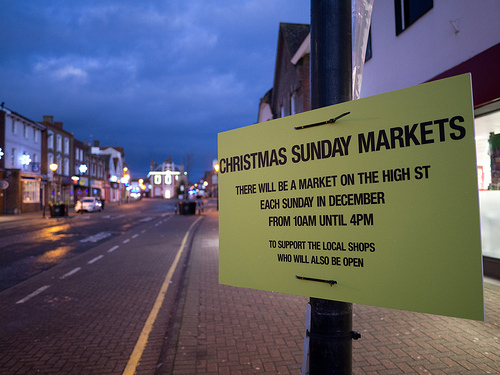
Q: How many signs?
A: 1.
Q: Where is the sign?
A: On the pole.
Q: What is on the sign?
A: Letters.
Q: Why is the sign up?
A: To tell people.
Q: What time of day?
A: Evening.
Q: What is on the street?
A: Cars.